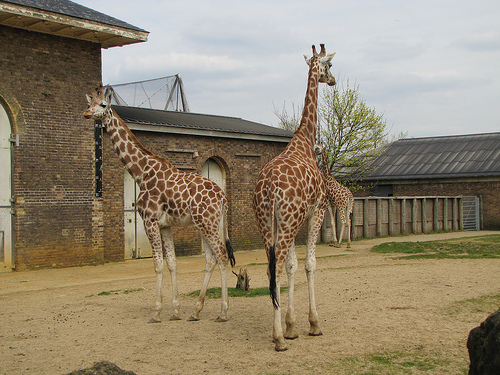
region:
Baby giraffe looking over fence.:
[318, 144, 353, 249]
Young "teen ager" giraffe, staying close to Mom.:
[82, 85, 237, 325]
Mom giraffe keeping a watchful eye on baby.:
[252, 43, 339, 352]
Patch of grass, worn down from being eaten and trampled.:
[373, 232, 498, 258]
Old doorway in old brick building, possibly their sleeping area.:
[195, 154, 230, 259]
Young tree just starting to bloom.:
[276, 81, 394, 192]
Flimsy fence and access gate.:
[315, 194, 485, 239]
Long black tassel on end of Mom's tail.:
[265, 245, 280, 312]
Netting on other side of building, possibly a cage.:
[104, 73, 194, 110]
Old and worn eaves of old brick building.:
[0, 2, 150, 50]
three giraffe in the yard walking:
[67, 41, 380, 358]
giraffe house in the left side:
[0, 2, 317, 267]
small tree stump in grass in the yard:
[188, 267, 285, 298]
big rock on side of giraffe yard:
[462, 307, 499, 373]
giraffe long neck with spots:
[90, 116, 154, 173]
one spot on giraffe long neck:
[138, 158, 148, 167]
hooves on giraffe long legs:
[260, 324, 342, 351]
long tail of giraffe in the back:
[265, 198, 278, 309]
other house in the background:
[342, 133, 499, 230]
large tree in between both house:
[280, 88, 386, 191]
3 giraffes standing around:
[67, 40, 422, 352]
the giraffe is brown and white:
[191, 52, 346, 307]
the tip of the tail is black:
[245, 232, 294, 312]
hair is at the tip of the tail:
[211, 230, 242, 277]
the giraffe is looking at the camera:
[52, 75, 124, 141]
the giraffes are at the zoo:
[67, 34, 404, 339]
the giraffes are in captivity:
[82, 36, 383, 350]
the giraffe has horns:
[283, 30, 330, 68]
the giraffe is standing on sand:
[199, 284, 432, 364]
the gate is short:
[348, 182, 498, 242]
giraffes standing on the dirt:
[71, 44, 365, 351]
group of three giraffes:
[78, 42, 382, 356]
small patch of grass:
[187, 274, 297, 304]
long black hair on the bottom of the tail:
[264, 244, 284, 315]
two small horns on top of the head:
[305, 41, 325, 59]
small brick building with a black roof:
[96, 89, 312, 265]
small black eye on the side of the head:
[94, 99, 111, 110]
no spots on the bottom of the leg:
[304, 263, 319, 315]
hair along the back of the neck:
[114, 111, 161, 164]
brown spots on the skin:
[144, 164, 217, 221]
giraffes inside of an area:
[27, 13, 477, 323]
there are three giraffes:
[76, 40, 380, 341]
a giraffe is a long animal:
[250, 44, 337, 353]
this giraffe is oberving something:
[73, 88, 241, 294]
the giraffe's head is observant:
[75, 81, 120, 126]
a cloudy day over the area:
[101, 6, 479, 124]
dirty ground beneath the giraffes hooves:
[31, 246, 473, 358]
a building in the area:
[371, 136, 492, 233]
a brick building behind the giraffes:
[3, 3, 148, 268]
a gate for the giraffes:
[323, 174, 480, 241]